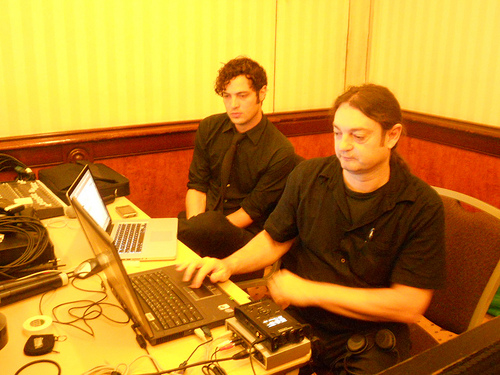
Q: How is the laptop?
A: On.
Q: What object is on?
A: Laptop.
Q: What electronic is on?
A: Laptop.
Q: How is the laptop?
A: On.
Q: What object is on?
A: Laptop.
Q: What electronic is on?
A: Laptop.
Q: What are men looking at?
A: Computer.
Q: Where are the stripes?
A: On wall.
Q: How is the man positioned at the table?
A: Sitting in a chair.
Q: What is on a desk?
A: A laptop.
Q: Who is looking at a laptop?
A: A man.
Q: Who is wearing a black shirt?
A: A man.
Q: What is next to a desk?
A: A chair.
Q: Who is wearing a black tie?
A: A man.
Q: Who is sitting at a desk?
A: A man.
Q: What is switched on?
A: The laptop.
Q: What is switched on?
A: The laptop.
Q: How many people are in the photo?
A: Two.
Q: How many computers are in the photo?
A: Two.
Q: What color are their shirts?
A: Black.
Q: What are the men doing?
A: Working on computer.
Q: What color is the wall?
A: Yellow.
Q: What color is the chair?
A: Brown.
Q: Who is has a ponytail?
A: The man in front.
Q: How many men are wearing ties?
A: One.